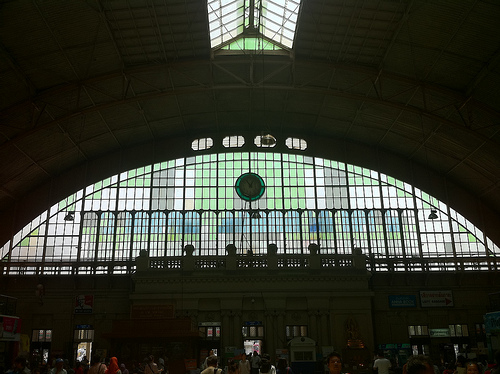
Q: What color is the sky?
A: Gray.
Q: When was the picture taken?
A: Daytime.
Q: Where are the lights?
A: On the ceiling.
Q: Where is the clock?
A: On the windows.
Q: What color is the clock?
A: Black and white.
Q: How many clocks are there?
A: One.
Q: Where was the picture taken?
A: In a station.